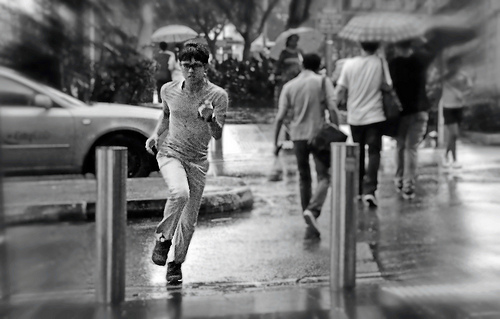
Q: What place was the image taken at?
A: It was taken at the street.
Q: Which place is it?
A: It is a street.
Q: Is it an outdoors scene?
A: Yes, it is outdoors.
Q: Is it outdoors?
A: Yes, it is outdoors.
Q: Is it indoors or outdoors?
A: It is outdoors.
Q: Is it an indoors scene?
A: No, it is outdoors.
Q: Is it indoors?
A: No, it is outdoors.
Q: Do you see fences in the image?
A: No, there are no fences.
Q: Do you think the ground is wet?
A: Yes, the ground is wet.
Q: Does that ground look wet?
A: Yes, the ground is wet.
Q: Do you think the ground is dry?
A: No, the ground is wet.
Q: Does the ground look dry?
A: No, the ground is wet.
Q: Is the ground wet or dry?
A: The ground is wet.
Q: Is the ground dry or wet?
A: The ground is wet.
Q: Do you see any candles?
A: No, there are no candles.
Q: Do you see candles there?
A: No, there are no candles.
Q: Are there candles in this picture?
A: No, there are no candles.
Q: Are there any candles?
A: No, there are no candles.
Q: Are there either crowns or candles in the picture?
A: No, there are no candles or crowns.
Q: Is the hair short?
A: Yes, the hair is short.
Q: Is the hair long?
A: No, the hair is short.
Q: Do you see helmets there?
A: No, there are no helmets.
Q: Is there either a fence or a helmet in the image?
A: No, there are no helmets or fences.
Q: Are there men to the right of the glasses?
A: Yes, there is a man to the right of the glasses.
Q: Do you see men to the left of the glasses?
A: No, the man is to the right of the glasses.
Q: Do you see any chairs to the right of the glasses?
A: No, there is a man to the right of the glasses.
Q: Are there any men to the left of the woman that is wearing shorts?
A: Yes, there is a man to the left of the woman.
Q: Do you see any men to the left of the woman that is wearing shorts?
A: Yes, there is a man to the left of the woman.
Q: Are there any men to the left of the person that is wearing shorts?
A: Yes, there is a man to the left of the woman.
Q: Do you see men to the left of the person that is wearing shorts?
A: Yes, there is a man to the left of the woman.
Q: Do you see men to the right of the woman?
A: No, the man is to the left of the woman.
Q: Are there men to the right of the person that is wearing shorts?
A: No, the man is to the left of the woman.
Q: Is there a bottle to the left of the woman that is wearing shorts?
A: No, there is a man to the left of the woman.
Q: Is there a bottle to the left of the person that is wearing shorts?
A: No, there is a man to the left of the woman.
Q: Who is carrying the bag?
A: The man is carrying the bag.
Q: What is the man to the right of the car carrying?
A: The man is carrying a bag.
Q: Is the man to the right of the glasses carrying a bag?
A: Yes, the man is carrying a bag.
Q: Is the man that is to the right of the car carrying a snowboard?
A: No, the man is carrying a bag.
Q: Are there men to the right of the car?
A: Yes, there is a man to the right of the car.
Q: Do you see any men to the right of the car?
A: Yes, there is a man to the right of the car.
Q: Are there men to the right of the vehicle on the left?
A: Yes, there is a man to the right of the car.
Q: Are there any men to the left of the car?
A: No, the man is to the right of the car.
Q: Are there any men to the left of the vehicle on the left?
A: No, the man is to the right of the car.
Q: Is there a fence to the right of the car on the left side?
A: No, there is a man to the right of the car.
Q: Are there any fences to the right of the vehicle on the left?
A: No, there is a man to the right of the car.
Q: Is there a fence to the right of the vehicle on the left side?
A: No, there is a man to the right of the car.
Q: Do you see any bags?
A: Yes, there is a bag.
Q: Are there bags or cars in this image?
A: Yes, there is a bag.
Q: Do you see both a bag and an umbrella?
A: Yes, there are both a bag and an umbrella.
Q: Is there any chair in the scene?
A: No, there are no chairs.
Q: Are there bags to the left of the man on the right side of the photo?
A: Yes, there is a bag to the left of the man.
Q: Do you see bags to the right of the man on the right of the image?
A: No, the bag is to the left of the man.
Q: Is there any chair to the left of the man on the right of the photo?
A: No, there is a bag to the left of the man.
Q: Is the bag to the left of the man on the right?
A: Yes, the bag is to the left of the man.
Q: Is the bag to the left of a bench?
A: No, the bag is to the left of the man.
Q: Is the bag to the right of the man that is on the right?
A: No, the bag is to the left of the man.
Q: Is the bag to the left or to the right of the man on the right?
A: The bag is to the left of the man.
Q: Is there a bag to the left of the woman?
A: Yes, there is a bag to the left of the woman.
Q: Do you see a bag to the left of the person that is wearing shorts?
A: Yes, there is a bag to the left of the woman.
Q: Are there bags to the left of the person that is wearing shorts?
A: Yes, there is a bag to the left of the woman.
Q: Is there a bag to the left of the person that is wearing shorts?
A: Yes, there is a bag to the left of the woman.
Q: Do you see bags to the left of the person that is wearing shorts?
A: Yes, there is a bag to the left of the woman.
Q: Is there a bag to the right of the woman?
A: No, the bag is to the left of the woman.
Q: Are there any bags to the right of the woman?
A: No, the bag is to the left of the woman.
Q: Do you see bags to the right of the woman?
A: No, the bag is to the left of the woman.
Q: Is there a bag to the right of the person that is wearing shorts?
A: No, the bag is to the left of the woman.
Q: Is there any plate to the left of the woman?
A: No, there is a bag to the left of the woman.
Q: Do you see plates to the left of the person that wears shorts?
A: No, there is a bag to the left of the woman.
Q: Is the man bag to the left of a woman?
A: Yes, the bag is to the left of a woman.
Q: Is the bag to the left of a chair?
A: No, the bag is to the left of a woman.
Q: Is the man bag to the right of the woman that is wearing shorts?
A: No, the bag is to the left of the woman.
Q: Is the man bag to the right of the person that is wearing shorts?
A: No, the bag is to the left of the woman.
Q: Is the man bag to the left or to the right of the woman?
A: The bag is to the left of the woman.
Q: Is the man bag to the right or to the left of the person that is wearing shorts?
A: The bag is to the left of the woman.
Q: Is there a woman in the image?
A: Yes, there is a woman.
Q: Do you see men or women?
A: Yes, there is a woman.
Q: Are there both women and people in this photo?
A: Yes, there are both a woman and a person.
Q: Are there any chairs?
A: No, there are no chairs.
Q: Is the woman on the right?
A: Yes, the woman is on the right of the image.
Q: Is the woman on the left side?
A: No, the woman is on the right of the image.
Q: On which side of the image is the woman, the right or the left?
A: The woman is on the right of the image.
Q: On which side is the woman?
A: The woman is on the right of the image.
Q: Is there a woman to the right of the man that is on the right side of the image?
A: Yes, there is a woman to the right of the man.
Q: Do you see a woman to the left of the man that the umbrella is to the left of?
A: No, the woman is to the right of the man.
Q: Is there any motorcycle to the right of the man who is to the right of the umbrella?
A: No, there is a woman to the right of the man.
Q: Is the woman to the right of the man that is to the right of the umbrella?
A: Yes, the woman is to the right of the man.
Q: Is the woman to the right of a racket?
A: No, the woman is to the right of the man.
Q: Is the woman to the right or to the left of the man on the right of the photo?
A: The woman is to the right of the man.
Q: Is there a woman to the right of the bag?
A: Yes, there is a woman to the right of the bag.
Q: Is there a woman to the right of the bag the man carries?
A: Yes, there is a woman to the right of the bag.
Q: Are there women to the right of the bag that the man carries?
A: Yes, there is a woman to the right of the bag.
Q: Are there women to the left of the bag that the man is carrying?
A: No, the woman is to the right of the bag.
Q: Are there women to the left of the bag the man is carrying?
A: No, the woman is to the right of the bag.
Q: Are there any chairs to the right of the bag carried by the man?
A: No, there is a woman to the right of the bag.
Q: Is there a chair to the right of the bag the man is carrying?
A: No, there is a woman to the right of the bag.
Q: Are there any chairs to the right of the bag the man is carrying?
A: No, there is a woman to the right of the bag.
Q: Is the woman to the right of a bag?
A: Yes, the woman is to the right of a bag.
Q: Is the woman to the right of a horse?
A: No, the woman is to the right of a bag.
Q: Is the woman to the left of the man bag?
A: No, the woman is to the right of the bag.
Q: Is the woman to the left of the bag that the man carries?
A: No, the woman is to the right of the bag.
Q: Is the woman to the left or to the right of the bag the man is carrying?
A: The woman is to the right of the bag.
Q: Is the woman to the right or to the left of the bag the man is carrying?
A: The woman is to the right of the bag.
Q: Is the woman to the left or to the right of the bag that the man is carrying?
A: The woman is to the right of the bag.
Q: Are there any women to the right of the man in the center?
A: Yes, there is a woman to the right of the man.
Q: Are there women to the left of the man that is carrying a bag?
A: No, the woman is to the right of the man.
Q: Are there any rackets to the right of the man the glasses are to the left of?
A: No, there is a woman to the right of the man.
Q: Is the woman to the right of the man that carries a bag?
A: Yes, the woman is to the right of the man.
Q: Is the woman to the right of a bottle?
A: No, the woman is to the right of the man.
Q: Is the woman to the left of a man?
A: No, the woman is to the right of a man.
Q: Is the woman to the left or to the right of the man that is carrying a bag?
A: The woman is to the right of the man.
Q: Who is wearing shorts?
A: The woman is wearing shorts.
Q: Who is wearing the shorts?
A: The woman is wearing shorts.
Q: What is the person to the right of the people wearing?
A: The woman is wearing shorts.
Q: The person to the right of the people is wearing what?
A: The woman is wearing shorts.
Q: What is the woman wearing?
A: The woman is wearing shorts.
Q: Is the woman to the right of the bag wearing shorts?
A: Yes, the woman is wearing shorts.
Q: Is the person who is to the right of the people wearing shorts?
A: Yes, the woman is wearing shorts.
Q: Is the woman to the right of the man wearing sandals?
A: No, the woman is wearing shorts.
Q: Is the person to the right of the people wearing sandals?
A: No, the woman is wearing shorts.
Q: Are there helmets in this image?
A: No, there are no helmets.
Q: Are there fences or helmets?
A: No, there are no helmets or fences.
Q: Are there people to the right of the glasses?
A: Yes, there is a person to the right of the glasses.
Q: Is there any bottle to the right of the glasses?
A: No, there is a person to the right of the glasses.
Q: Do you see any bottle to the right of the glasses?
A: No, there is a person to the right of the glasses.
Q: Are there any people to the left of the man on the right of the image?
A: Yes, there is a person to the left of the man.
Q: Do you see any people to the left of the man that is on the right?
A: Yes, there is a person to the left of the man.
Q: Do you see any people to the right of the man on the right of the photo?
A: No, the person is to the left of the man.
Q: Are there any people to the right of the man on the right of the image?
A: No, the person is to the left of the man.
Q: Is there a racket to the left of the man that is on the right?
A: No, there is a person to the left of the man.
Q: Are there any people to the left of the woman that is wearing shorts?
A: Yes, there is a person to the left of the woman.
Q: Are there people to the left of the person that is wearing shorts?
A: Yes, there is a person to the left of the woman.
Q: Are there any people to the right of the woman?
A: No, the person is to the left of the woman.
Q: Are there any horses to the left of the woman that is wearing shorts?
A: No, there is a person to the left of the woman.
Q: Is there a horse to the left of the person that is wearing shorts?
A: No, there is a person to the left of the woman.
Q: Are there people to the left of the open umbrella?
A: Yes, there is a person to the left of the umbrella.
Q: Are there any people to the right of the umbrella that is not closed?
A: No, the person is to the left of the umbrella.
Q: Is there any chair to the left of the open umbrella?
A: No, there is a person to the left of the umbrella.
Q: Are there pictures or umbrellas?
A: Yes, there is an umbrella.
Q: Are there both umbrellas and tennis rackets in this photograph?
A: No, there is an umbrella but no rackets.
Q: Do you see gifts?
A: No, there are no gifts.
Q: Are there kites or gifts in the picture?
A: No, there are no gifts or kites.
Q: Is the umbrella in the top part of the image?
A: Yes, the umbrella is in the top of the image.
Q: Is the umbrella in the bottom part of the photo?
A: No, the umbrella is in the top of the image.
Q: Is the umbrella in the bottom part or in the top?
A: The umbrella is in the top of the image.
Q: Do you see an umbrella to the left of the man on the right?
A: Yes, there is an umbrella to the left of the man.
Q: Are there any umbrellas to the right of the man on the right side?
A: No, the umbrella is to the left of the man.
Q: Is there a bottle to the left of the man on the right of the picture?
A: No, there is an umbrella to the left of the man.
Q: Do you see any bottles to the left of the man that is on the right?
A: No, there is an umbrella to the left of the man.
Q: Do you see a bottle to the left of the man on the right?
A: No, there is an umbrella to the left of the man.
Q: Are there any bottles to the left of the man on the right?
A: No, there is an umbrella to the left of the man.